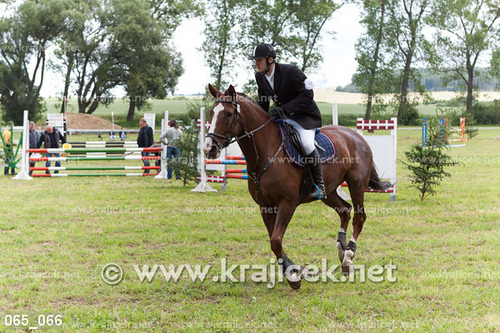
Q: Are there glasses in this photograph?
A: No, there are no glasses.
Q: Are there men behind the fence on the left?
A: Yes, there is a man behind the fence.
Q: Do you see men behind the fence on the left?
A: Yes, there is a man behind the fence.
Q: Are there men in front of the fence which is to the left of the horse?
A: No, the man is behind the fence.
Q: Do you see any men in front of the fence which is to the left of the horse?
A: No, the man is behind the fence.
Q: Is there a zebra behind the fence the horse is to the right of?
A: No, there is a man behind the fence.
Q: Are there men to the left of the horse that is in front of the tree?
A: Yes, there is a man to the left of the horse.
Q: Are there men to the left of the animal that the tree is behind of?
A: Yes, there is a man to the left of the horse.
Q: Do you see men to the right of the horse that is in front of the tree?
A: No, the man is to the left of the horse.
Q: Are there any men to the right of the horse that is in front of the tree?
A: No, the man is to the left of the horse.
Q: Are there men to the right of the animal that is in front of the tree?
A: No, the man is to the left of the horse.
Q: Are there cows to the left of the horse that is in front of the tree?
A: No, there is a man to the left of the horse.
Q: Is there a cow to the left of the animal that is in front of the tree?
A: No, there is a man to the left of the horse.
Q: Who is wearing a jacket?
A: The man is wearing a jacket.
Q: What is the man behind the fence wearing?
A: The man is wearing a jacket.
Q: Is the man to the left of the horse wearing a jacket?
A: Yes, the man is wearing a jacket.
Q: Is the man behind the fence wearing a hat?
A: No, the man is wearing a jacket.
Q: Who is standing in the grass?
A: The man is standing in the grass.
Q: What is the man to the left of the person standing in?
A: The man is standing in the grass.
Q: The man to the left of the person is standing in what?
A: The man is standing in the grass.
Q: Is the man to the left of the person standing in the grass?
A: Yes, the man is standing in the grass.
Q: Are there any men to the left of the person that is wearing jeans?
A: Yes, there is a man to the left of the person.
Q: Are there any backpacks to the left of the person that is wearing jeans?
A: No, there is a man to the left of the person.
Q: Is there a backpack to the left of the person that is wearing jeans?
A: No, there is a man to the left of the person.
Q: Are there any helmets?
A: Yes, there is a helmet.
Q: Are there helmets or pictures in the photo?
A: Yes, there is a helmet.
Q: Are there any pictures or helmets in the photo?
A: Yes, there is a helmet.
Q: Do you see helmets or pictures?
A: Yes, there is a helmet.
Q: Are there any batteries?
A: No, there are no batteries.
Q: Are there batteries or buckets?
A: No, there are no batteries or buckets.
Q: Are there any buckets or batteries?
A: No, there are no batteries or buckets.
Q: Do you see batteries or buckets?
A: No, there are no batteries or buckets.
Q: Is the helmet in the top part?
A: Yes, the helmet is in the top of the image.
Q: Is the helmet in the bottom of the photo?
A: No, the helmet is in the top of the image.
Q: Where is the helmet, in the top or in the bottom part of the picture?
A: The helmet is in the top of the image.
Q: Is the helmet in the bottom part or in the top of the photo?
A: The helmet is in the top of the image.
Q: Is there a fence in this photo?
A: Yes, there is a fence.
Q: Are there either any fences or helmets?
A: Yes, there is a fence.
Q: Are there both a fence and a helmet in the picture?
A: Yes, there are both a fence and a helmet.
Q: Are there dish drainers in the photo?
A: No, there are no dish drainers.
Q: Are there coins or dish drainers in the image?
A: No, there are no dish drainers or coins.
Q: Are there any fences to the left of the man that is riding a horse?
A: Yes, there is a fence to the left of the man.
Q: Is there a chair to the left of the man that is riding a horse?
A: No, there is a fence to the left of the man.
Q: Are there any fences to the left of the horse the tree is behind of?
A: Yes, there is a fence to the left of the horse.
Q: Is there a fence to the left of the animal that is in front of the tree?
A: Yes, there is a fence to the left of the horse.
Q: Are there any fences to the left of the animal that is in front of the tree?
A: Yes, there is a fence to the left of the horse.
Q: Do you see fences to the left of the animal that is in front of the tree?
A: Yes, there is a fence to the left of the horse.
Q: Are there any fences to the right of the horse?
A: No, the fence is to the left of the horse.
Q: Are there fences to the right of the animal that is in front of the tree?
A: No, the fence is to the left of the horse.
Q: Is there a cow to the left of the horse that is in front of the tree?
A: No, there is a fence to the left of the horse.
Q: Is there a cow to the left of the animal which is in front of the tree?
A: No, there is a fence to the left of the horse.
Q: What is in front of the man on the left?
A: The fence is in front of the man.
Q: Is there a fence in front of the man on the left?
A: Yes, there is a fence in front of the man.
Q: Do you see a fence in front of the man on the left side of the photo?
A: Yes, there is a fence in front of the man.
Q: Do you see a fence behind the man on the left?
A: No, the fence is in front of the man.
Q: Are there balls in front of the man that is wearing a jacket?
A: No, there is a fence in front of the man.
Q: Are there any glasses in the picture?
A: No, there are no glasses.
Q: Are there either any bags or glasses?
A: No, there are no glasses or bags.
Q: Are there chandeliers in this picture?
A: No, there are no chandeliers.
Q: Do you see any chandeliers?
A: No, there are no chandeliers.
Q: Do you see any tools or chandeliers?
A: No, there are no chandeliers or tools.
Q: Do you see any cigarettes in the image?
A: No, there are no cigarettes.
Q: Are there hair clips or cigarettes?
A: No, there are no cigarettes or hair clips.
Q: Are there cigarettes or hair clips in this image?
A: No, there are no cigarettes or hair clips.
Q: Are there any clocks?
A: No, there are no clocks.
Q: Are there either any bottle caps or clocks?
A: No, there are no clocks or bottle caps.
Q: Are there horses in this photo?
A: Yes, there is a horse.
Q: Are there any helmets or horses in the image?
A: Yes, there is a horse.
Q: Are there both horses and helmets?
A: Yes, there are both a horse and a helmet.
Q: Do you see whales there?
A: No, there are no whales.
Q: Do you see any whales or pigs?
A: No, there are no whales or pigs.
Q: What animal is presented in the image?
A: The animal is a horse.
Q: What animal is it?
A: The animal is a horse.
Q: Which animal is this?
A: This is a horse.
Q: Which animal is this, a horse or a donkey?
A: This is a horse.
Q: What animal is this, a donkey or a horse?
A: This is a horse.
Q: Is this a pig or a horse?
A: This is a horse.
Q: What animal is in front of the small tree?
A: The horse is in front of the tree.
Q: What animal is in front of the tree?
A: The horse is in front of the tree.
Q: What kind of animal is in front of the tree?
A: The animal is a horse.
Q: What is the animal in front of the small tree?
A: The animal is a horse.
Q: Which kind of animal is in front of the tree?
A: The animal is a horse.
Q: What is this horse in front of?
A: The horse is in front of the tree.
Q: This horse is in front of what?
A: The horse is in front of the tree.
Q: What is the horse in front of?
A: The horse is in front of the tree.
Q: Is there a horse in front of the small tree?
A: Yes, there is a horse in front of the tree.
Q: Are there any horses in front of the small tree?
A: Yes, there is a horse in front of the tree.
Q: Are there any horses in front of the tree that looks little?
A: Yes, there is a horse in front of the tree.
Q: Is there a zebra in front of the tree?
A: No, there is a horse in front of the tree.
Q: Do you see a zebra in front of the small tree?
A: No, there is a horse in front of the tree.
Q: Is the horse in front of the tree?
A: Yes, the horse is in front of the tree.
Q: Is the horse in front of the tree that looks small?
A: Yes, the horse is in front of the tree.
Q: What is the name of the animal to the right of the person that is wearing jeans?
A: The animal is a horse.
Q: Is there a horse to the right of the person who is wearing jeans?
A: Yes, there is a horse to the right of the person.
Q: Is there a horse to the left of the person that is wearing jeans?
A: No, the horse is to the right of the person.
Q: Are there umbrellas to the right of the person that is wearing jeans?
A: No, there is a horse to the right of the person.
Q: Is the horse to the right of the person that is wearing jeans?
A: Yes, the horse is to the right of the person.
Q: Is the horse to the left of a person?
A: No, the horse is to the right of a person.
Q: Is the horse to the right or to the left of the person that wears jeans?
A: The horse is to the right of the person.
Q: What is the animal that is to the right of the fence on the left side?
A: The animal is a horse.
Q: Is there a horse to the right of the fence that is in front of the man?
A: Yes, there is a horse to the right of the fence.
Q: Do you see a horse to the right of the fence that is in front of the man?
A: Yes, there is a horse to the right of the fence.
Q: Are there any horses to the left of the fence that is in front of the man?
A: No, the horse is to the right of the fence.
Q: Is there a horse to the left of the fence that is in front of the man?
A: No, the horse is to the right of the fence.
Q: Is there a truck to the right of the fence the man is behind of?
A: No, there is a horse to the right of the fence.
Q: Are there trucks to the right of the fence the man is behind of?
A: No, there is a horse to the right of the fence.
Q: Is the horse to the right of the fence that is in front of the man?
A: Yes, the horse is to the right of the fence.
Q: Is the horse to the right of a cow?
A: No, the horse is to the right of the fence.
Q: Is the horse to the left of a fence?
A: No, the horse is to the right of a fence.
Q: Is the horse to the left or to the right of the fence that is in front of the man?
A: The horse is to the right of the fence.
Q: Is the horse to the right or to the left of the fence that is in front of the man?
A: The horse is to the right of the fence.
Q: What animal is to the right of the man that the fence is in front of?
A: The animal is a horse.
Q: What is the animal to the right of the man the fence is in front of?
A: The animal is a horse.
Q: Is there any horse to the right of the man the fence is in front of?
A: Yes, there is a horse to the right of the man.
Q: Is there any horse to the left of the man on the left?
A: No, the horse is to the right of the man.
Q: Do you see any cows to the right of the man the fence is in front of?
A: No, there is a horse to the right of the man.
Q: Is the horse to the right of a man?
A: Yes, the horse is to the right of a man.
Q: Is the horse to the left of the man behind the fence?
A: No, the horse is to the right of the man.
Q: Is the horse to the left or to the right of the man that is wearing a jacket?
A: The horse is to the right of the man.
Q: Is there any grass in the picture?
A: Yes, there is grass.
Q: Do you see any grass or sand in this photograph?
A: Yes, there is grass.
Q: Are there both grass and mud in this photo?
A: No, there is grass but no mud.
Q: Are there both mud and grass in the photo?
A: No, there is grass but no mud.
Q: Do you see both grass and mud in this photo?
A: No, there is grass but no mud.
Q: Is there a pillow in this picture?
A: No, there are no pillows.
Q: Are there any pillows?
A: No, there are no pillows.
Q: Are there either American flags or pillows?
A: No, there are no pillows or American flags.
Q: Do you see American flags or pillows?
A: No, there are no pillows or American flags.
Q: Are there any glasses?
A: No, there are no glasses.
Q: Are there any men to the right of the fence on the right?
A: No, the man is to the left of the fence.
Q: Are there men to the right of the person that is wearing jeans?
A: Yes, there is a man to the right of the person.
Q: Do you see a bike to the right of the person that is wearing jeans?
A: No, there is a man to the right of the person.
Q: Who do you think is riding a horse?
A: The man is riding a horse.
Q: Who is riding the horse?
A: The man is riding a horse.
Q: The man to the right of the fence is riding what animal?
A: The man is riding a horse.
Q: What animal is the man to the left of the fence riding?
A: The man is riding a horse.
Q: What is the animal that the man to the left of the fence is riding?
A: The animal is a horse.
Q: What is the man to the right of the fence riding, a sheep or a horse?
A: The man is riding a horse.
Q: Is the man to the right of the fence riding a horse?
A: Yes, the man is riding a horse.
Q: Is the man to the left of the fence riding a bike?
A: No, the man is riding a horse.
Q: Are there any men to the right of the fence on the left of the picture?
A: Yes, there is a man to the right of the fence.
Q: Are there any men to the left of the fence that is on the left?
A: No, the man is to the right of the fence.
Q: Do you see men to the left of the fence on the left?
A: No, the man is to the right of the fence.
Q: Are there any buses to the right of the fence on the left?
A: No, there is a man to the right of the fence.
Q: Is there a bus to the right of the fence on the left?
A: No, there is a man to the right of the fence.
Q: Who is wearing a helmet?
A: The man is wearing a helmet.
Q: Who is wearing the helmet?
A: The man is wearing a helmet.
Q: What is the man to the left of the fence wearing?
A: The man is wearing a helmet.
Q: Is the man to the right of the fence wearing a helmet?
A: Yes, the man is wearing a helmet.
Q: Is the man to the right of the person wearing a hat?
A: No, the man is wearing a helmet.